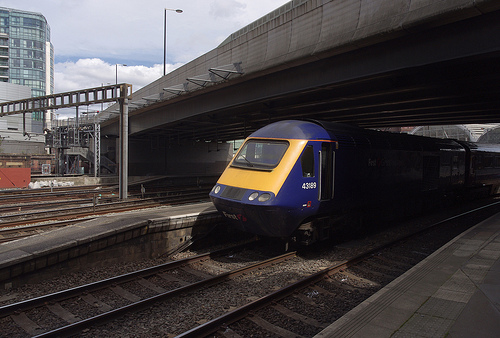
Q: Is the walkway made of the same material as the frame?
A: No, the walkway is made of concrete and the frame is made of metal.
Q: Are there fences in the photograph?
A: No, there are no fences.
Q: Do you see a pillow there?
A: No, there are no pillows.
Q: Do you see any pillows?
A: No, there are no pillows.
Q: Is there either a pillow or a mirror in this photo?
A: No, there are no pillows or mirrors.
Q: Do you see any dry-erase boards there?
A: No, there are no dry-erase boards.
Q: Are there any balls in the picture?
A: No, there are no balls.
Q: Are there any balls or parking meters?
A: No, there are no balls or parking meters.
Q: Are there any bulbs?
A: No, there are no bulbs.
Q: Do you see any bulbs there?
A: No, there are no bulbs.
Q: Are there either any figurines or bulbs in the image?
A: No, there are no bulbs or figurines.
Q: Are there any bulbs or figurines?
A: No, there are no bulbs or figurines.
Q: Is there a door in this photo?
A: Yes, there is a door.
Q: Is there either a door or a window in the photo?
A: Yes, there is a door.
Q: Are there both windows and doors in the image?
A: Yes, there are both a door and a window.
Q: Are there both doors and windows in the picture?
A: Yes, there are both a door and a window.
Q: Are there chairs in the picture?
A: No, there are no chairs.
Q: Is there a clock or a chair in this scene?
A: No, there are no chairs or clocks.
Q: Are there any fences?
A: No, there are no fences.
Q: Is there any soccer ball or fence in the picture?
A: No, there are no fences or soccer balls.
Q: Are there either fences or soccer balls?
A: No, there are no fences or soccer balls.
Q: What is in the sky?
A: The clouds are in the sky.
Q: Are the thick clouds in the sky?
A: Yes, the clouds are in the sky.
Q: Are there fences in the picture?
A: No, there are no fences.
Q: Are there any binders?
A: No, there are no binders.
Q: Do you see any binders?
A: No, there are no binders.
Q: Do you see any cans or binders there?
A: No, there are no binders or cans.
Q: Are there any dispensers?
A: No, there are no dispensers.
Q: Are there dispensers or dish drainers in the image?
A: No, there are no dispensers or dish drainers.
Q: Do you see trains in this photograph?
A: Yes, there is a train.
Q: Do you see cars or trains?
A: Yes, there is a train.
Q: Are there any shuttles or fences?
A: No, there are no fences or shuttles.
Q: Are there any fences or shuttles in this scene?
A: No, there are no fences or shuttles.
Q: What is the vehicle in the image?
A: The vehicle is a train.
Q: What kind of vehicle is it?
A: The vehicle is a train.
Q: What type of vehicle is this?
A: This is a train.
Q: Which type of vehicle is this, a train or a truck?
A: This is a train.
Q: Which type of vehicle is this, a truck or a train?
A: This is a train.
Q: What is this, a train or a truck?
A: This is a train.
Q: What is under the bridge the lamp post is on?
A: The train is under the bridge.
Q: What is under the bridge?
A: The train is under the bridge.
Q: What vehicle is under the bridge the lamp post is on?
A: The vehicle is a train.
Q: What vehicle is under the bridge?
A: The vehicle is a train.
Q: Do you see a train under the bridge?
A: Yes, there is a train under the bridge.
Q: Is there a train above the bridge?
A: No, the train is under the bridge.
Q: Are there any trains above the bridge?
A: No, the train is under the bridge.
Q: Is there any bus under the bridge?
A: No, there is a train under the bridge.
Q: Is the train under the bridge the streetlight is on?
A: Yes, the train is under the bridge.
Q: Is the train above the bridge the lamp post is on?
A: No, the train is under the bridge.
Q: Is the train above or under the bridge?
A: The train is under the bridge.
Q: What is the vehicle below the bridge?
A: The vehicle is a train.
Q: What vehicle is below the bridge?
A: The vehicle is a train.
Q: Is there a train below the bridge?
A: Yes, there is a train below the bridge.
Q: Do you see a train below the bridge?
A: Yes, there is a train below the bridge.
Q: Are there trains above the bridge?
A: No, the train is below the bridge.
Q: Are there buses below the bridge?
A: No, there is a train below the bridge.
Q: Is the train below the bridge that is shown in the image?
A: Yes, the train is below the bridge.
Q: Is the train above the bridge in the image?
A: No, the train is below the bridge.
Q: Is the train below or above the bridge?
A: The train is below the bridge.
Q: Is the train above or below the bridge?
A: The train is below the bridge.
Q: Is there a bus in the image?
A: No, there are no buses.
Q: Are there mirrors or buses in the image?
A: No, there are no buses or mirrors.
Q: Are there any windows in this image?
A: Yes, there is a window.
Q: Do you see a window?
A: Yes, there is a window.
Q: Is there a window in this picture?
A: Yes, there is a window.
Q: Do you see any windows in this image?
A: Yes, there is a window.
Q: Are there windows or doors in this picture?
A: Yes, there is a window.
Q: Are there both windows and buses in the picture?
A: No, there is a window but no buses.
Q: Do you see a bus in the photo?
A: No, there are no buses.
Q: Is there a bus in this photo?
A: No, there are no buses.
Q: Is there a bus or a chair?
A: No, there are no buses or chairs.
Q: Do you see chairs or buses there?
A: No, there are no buses or chairs.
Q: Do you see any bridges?
A: Yes, there is a bridge.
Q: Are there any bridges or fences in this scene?
A: Yes, there is a bridge.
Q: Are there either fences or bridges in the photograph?
A: Yes, there is a bridge.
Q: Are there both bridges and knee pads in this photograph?
A: No, there is a bridge but no knee pads.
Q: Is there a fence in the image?
A: No, there are no fences.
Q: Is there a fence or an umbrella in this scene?
A: No, there are no fences or umbrellas.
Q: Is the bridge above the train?
A: Yes, the bridge is above the train.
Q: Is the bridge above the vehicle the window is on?
A: Yes, the bridge is above the train.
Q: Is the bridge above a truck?
A: No, the bridge is above the train.